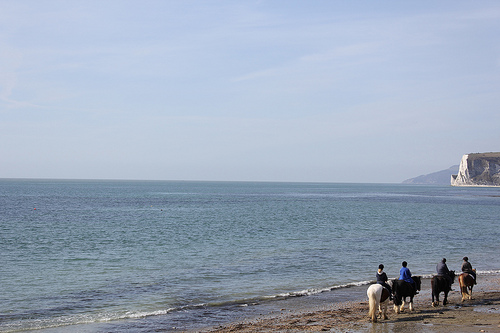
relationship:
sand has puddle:
[197, 277, 499, 332] [470, 300, 499, 319]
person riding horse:
[374, 260, 393, 304] [364, 277, 400, 324]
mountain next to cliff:
[450, 150, 500, 192] [448, 172, 460, 188]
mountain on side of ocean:
[450, 150, 500, 192] [2, 179, 498, 332]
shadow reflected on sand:
[379, 313, 437, 326] [197, 277, 499, 332]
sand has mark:
[197, 277, 499, 332] [419, 316, 435, 328]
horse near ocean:
[364, 277, 400, 324] [2, 179, 498, 332]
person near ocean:
[374, 260, 393, 304] [2, 179, 498, 332]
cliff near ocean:
[448, 172, 460, 188] [2, 179, 498, 332]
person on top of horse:
[374, 260, 393, 304] [364, 277, 400, 324]